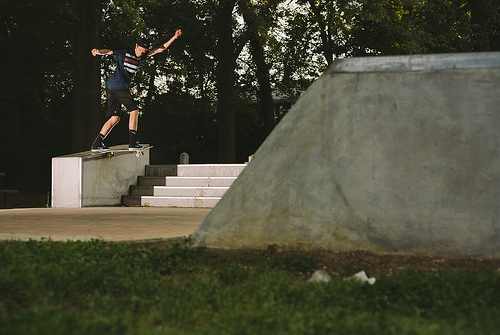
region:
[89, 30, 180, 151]
skater is on skateboard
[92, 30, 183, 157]
skater is in the air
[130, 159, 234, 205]
stairs are near the skater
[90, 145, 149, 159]
skater is grinding skateboard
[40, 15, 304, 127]
trees are in the background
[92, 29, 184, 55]
skaters hands are in the air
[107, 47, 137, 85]
skater has a blue shirt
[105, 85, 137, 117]
skater has black shorts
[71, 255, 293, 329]
grass is green in color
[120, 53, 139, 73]
skater has stripes on shirt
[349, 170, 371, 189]
part of a wall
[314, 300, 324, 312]
part of a lawn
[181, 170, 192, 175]
part of a stair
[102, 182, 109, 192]
part of a wall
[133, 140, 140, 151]
part of a sock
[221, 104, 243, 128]
part of a stem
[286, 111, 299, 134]
edge of a wall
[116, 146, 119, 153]
part of a board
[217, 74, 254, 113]
part of a tree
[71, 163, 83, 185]
edge of a wall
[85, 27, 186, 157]
A skater skating on board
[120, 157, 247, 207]
A set of stairs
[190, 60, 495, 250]
A concrete skate rider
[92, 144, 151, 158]
A skate board doing trick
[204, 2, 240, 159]
A large tree trunk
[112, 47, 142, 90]
A skate boarders shirt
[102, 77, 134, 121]
Black mans skate shorts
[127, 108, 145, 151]
A amns right leg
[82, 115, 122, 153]
A mans left leg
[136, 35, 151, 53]
A black base ball cap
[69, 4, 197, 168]
Man on a skateboard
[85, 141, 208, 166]
Black and white skareboard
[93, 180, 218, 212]
Shadow on the stairs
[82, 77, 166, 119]
Short black shorts on man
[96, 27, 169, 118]
Man wearing a blue shirt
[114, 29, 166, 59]
Man wearing a black hat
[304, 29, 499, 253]
Slab of concrete in ground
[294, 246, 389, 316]
Trash on the ground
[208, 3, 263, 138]
Large tree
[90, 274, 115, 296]
Small patch of green grass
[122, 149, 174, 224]
Shadow on the pavement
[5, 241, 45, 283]
PAtch of green grass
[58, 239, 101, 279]
PAtch of green grass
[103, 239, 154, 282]
PAtch of green grass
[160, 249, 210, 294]
PAtch of green grass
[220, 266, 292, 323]
PAtch of green grass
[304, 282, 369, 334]
PAtch of green grass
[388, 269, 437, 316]
PAtch of green grass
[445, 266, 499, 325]
PAtch of green grass